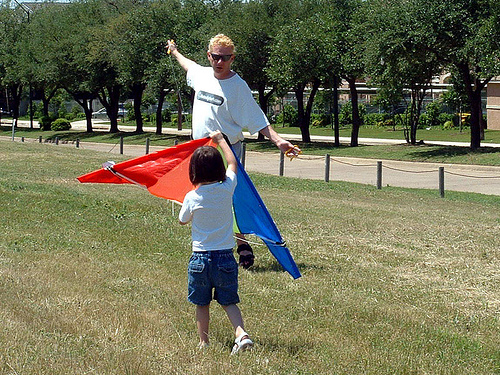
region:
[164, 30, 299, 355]
a man and a young girl in a park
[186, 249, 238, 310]
young girl wearing jeans shorts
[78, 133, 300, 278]
young girl holding a kite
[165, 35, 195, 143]
man holding a kite's string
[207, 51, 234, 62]
man wearing black sunglasses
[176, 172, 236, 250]
young girl wearing a white shirt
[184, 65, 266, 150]
man wearing a white shirt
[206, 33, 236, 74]
man with blond curly hair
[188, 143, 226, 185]
young girl with short brown hair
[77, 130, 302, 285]
a blue and red kite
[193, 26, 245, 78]
head of a man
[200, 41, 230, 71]
sunglasses on man's face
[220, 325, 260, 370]
foot of the girl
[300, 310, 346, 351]
green grass next to girl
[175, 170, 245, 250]
white shirt on girl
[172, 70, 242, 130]
shirt on the man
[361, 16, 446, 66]
leaves on the tree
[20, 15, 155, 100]
many trees in the background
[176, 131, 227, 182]
head of the girl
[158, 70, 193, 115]
string of the kite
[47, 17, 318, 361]
a man and child flying a kite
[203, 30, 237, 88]
a man wearing sunglasses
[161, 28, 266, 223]
a man looking down at a child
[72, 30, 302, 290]
a man looking down at a kite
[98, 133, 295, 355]
a child holding a kite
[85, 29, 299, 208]
a man holding the strings of a kite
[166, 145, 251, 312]
a child wearing jean shorts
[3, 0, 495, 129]
a row of trees in a park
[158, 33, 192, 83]
the arm of a man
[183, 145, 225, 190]
the head of a child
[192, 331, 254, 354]
Child is wearing shoes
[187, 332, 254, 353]
Child is wearing white shoes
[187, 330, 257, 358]
Child is wearing sandals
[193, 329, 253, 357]
Child is wearing white sandals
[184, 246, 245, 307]
Child is wearing shorts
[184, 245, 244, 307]
Child is wearing blue shorts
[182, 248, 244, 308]
Child is wearing denim shorts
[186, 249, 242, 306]
Child is wearing blue denim shorts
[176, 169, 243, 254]
Child is wearing a shirt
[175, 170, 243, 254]
Child is wearing a white shirt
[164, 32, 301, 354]
the people standing on the grass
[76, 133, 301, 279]
the red and blue kite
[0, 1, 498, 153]
the trees lined up in a row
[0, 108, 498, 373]
the grass on the ground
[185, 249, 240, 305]
the denim shorts on the small child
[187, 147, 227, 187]
the hair on the small child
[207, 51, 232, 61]
the sunglasses on the man's face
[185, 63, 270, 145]
the short sleeved shirt on the man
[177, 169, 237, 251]
the short sleeved shirt on the small child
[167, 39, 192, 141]
the kite's string being stretched out